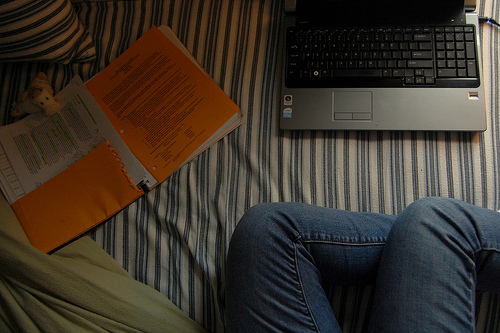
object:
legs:
[224, 195, 500, 332]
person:
[0, 193, 500, 331]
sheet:
[1, 1, 499, 330]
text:
[15, 104, 93, 177]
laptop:
[280, 1, 485, 135]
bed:
[1, 0, 499, 332]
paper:
[88, 27, 237, 182]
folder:
[0, 27, 243, 253]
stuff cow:
[9, 71, 61, 118]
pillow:
[1, 1, 97, 67]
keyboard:
[286, 24, 479, 89]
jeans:
[222, 196, 495, 332]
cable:
[480, 17, 499, 31]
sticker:
[284, 94, 294, 106]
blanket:
[1, 195, 202, 330]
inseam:
[291, 234, 382, 330]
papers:
[2, 77, 148, 199]